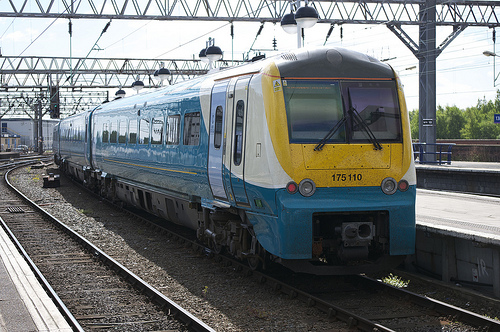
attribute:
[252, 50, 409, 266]
front — yellow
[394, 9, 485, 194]
pole — metal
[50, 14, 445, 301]
locomotive — electric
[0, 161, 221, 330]
train tracks — empty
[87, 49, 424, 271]
train — long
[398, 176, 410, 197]
light — yellow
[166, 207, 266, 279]
wheels — black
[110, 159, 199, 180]
strip — yellow